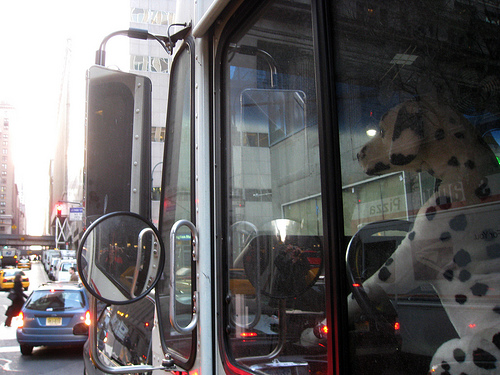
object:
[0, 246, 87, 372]
street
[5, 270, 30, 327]
person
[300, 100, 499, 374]
dog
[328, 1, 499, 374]
window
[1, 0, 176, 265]
buildings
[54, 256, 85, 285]
truck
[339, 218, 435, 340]
steering wheel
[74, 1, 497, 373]
bus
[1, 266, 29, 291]
taxi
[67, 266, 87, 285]
man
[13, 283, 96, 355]
car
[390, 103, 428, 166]
ear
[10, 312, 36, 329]
light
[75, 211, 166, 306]
mirror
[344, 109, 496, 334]
dalmation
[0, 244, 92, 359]
traffic jam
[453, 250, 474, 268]
black spot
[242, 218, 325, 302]
reflection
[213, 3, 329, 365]
glass